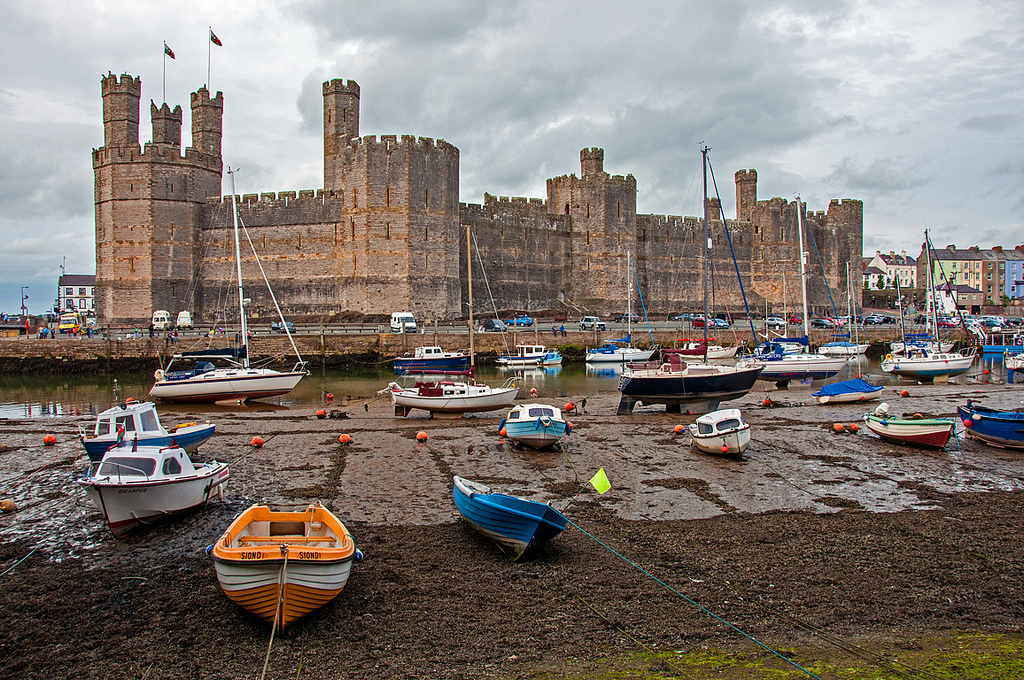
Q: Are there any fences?
A: No, there are no fences.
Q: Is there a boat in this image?
A: Yes, there is a boat.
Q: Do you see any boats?
A: Yes, there is a boat.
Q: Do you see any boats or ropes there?
A: Yes, there is a boat.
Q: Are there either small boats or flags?
A: Yes, there is a small boat.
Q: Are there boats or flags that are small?
A: Yes, the boat is small.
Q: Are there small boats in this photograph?
A: Yes, there is a small boat.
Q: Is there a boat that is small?
A: Yes, there is a boat that is small.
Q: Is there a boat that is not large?
A: Yes, there is a small boat.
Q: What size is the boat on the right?
A: The boat is small.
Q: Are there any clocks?
A: No, there are no clocks.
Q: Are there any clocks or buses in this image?
A: No, there are no clocks or buses.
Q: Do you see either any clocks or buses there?
A: No, there are no clocks or buses.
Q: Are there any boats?
A: Yes, there is a boat.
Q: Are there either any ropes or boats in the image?
A: Yes, there is a boat.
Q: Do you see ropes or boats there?
A: Yes, there is a boat.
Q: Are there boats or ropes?
A: Yes, there is a boat.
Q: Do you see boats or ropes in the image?
A: Yes, there is a boat.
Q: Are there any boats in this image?
A: Yes, there is a boat.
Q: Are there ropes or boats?
A: Yes, there is a boat.